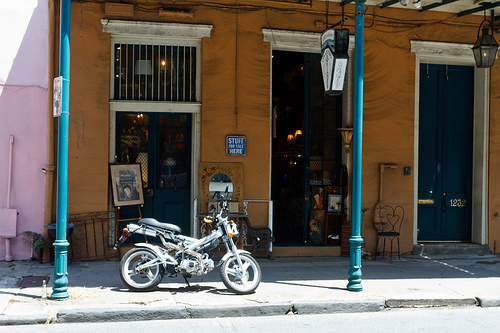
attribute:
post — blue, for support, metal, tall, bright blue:
[50, 0, 73, 302]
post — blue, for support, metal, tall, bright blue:
[348, 5, 365, 294]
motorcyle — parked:
[112, 188, 263, 296]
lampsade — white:
[133, 60, 157, 76]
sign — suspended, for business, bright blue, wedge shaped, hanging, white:
[320, 27, 351, 94]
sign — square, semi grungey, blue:
[227, 135, 248, 153]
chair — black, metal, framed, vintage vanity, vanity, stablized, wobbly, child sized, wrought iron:
[375, 204, 405, 260]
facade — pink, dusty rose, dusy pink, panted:
[0, 1, 50, 260]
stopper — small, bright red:
[381, 256, 390, 259]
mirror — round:
[206, 171, 237, 200]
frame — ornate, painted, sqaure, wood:
[198, 163, 243, 210]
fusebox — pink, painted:
[1, 210, 18, 238]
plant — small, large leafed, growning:
[19, 229, 46, 260]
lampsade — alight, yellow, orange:
[136, 153, 150, 186]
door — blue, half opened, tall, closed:
[417, 65, 474, 240]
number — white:
[449, 198, 467, 207]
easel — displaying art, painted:
[109, 163, 145, 239]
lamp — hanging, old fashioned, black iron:
[471, 16, 497, 68]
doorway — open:
[270, 48, 351, 251]